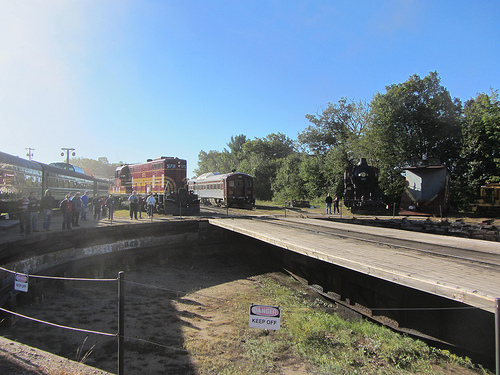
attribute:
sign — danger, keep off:
[243, 299, 282, 330]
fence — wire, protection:
[0, 259, 499, 373]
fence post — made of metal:
[109, 263, 128, 372]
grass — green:
[4, 253, 480, 373]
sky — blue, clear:
[0, 1, 497, 178]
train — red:
[188, 170, 255, 208]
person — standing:
[61, 193, 75, 233]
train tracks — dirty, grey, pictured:
[255, 214, 499, 281]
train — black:
[1, 148, 110, 222]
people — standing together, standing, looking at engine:
[15, 188, 161, 244]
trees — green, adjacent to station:
[186, 70, 498, 221]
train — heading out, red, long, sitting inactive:
[110, 158, 191, 209]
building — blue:
[403, 155, 448, 204]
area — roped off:
[9, 252, 482, 375]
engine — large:
[130, 155, 203, 220]